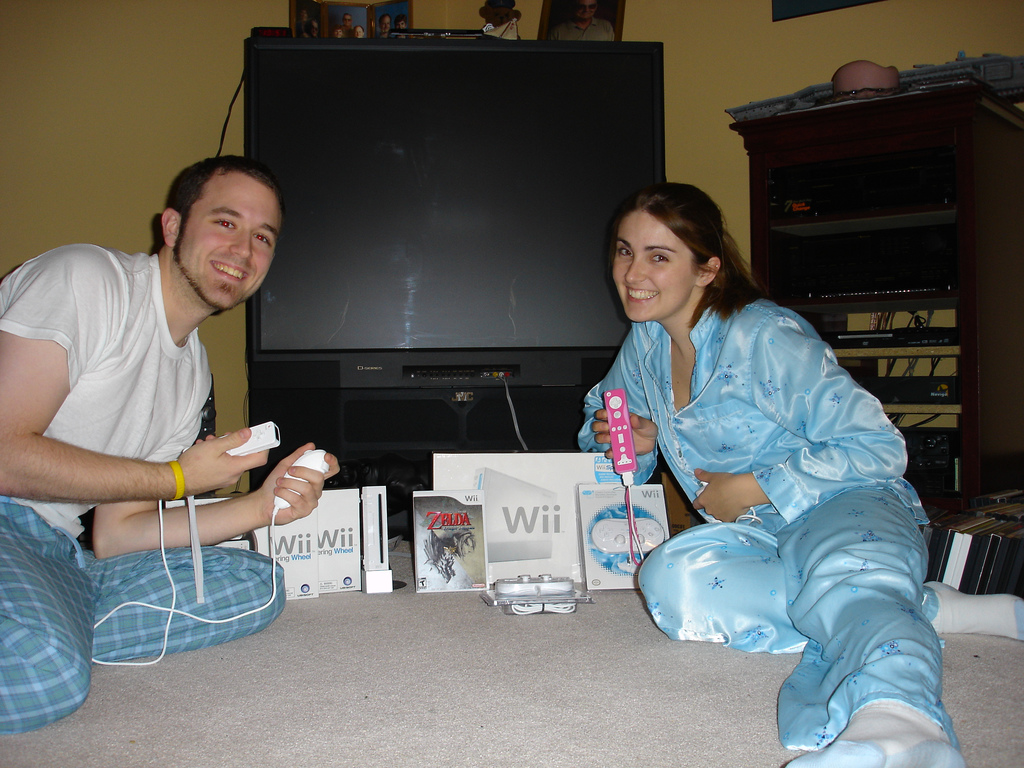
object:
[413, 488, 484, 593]
game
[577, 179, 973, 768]
woman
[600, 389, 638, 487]
remote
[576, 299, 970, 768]
pajamas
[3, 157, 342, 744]
man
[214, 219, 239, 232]
eyes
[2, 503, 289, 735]
pants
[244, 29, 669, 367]
tv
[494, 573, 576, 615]
controllers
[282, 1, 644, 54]
pictures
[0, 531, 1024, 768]
floor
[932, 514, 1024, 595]
books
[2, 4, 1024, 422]
wall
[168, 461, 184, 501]
bracelet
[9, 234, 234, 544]
shirt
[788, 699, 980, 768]
socks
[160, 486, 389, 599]
boxes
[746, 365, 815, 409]
blue